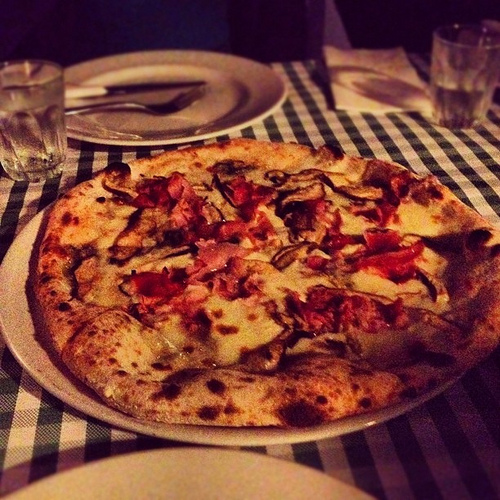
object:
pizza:
[36, 138, 500, 428]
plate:
[0, 168, 481, 447]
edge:
[123, 425, 363, 447]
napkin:
[322, 45, 433, 113]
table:
[0, 57, 500, 500]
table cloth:
[0, 57, 500, 500]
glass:
[430, 20, 500, 127]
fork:
[64, 86, 205, 116]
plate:
[62, 49, 287, 147]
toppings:
[132, 164, 210, 247]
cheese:
[142, 294, 286, 360]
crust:
[35, 194, 75, 360]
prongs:
[174, 90, 202, 110]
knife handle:
[64, 87, 108, 100]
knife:
[63, 79, 205, 99]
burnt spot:
[270, 398, 332, 425]